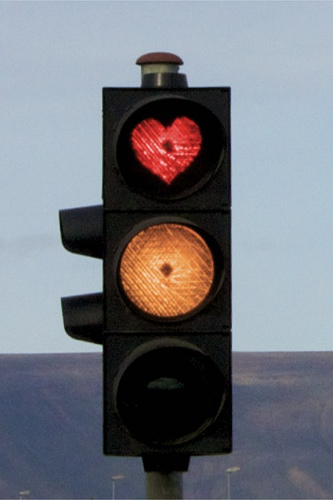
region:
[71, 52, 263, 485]
the lights are visible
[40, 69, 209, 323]
the lights are visible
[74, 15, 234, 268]
the lights are visible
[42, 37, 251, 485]
a black traffic light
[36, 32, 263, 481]
traffic light has three colors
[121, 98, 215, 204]
red color of traffic light is heart shape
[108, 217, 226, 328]
round orange light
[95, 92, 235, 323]
red and orange traffic light are bright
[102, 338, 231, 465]
green light of traffic light is turn off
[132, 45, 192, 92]
red top on traffic light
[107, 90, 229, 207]
a black circle around red light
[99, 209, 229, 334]
an orange circle around red light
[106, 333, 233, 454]
a black circle around green light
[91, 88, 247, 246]
a traffic light shaped like a heart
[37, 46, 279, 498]
traffic lights on a metal post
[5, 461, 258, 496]
street lights in the background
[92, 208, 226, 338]
a yellow traffic light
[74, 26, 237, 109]
top of a metal post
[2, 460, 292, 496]
three street lights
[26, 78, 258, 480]
a double-sided black street light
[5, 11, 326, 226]
clear blue sky in the background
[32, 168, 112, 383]
street lights on the left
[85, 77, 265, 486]
street light with yellow and red light on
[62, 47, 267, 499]
traffic light with black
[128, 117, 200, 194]
heart on traffic light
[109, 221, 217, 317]
yellow round traffic light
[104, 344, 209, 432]
round circular light on bottom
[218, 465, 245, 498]
street light on bottom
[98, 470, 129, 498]
street light on bottom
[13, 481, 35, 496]
street light on bottom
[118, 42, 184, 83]
red button on top of light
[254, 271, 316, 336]
blue hazy sky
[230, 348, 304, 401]
flat skyline in the background